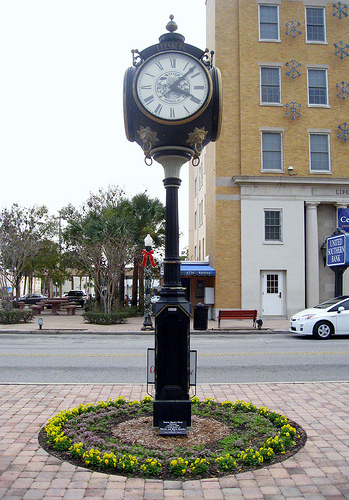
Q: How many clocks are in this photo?
A: One.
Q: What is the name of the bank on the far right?
A: United Southern Bank.